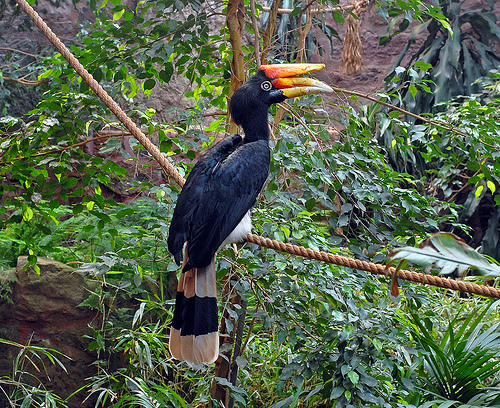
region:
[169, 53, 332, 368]
A horn bill in the wild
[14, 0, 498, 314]
A twisted horizontal rope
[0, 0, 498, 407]
The green vegetated grounds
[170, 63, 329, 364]
A long tailed hornbill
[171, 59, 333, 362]
The orange beaked hornbill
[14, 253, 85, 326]
The gray weather beaten rock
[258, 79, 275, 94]
The rounded horn-bill eyes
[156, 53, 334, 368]
The young black and white horn-bill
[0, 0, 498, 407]
The dirt covered background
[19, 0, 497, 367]
A young horn-bill on a line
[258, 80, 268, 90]
Bird has blue eye.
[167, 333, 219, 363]
Tip of tail feathers are tan.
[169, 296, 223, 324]
Black stripe on tail feathers.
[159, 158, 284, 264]
Large bird perched on rope.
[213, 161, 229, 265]
Black feathers on bird's wing.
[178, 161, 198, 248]
Black feathers on bird's wing.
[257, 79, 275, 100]
Yellow ring around bird's eye.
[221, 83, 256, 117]
Bird has black head.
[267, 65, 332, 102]
Bird has red and orange beak.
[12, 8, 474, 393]
ground covered with dirt, rocks and green plants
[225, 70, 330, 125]
round black head with orange beak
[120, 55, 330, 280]
large bird perched on brown rope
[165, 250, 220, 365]
thick black stripe across white tail feathers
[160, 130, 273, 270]
long black wings close to bird's body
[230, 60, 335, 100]
flat orange appendage over beak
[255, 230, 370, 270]
line of slants across brown rope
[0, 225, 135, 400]
gray rock surrounded by narrow and triangular leaves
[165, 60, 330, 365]
black and white bird balanced on twisted fibers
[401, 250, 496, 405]
plant with long and narrow leaves growing under rope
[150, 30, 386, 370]
A very large bird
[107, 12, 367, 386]
A bird sitting on a rope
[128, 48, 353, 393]
Large black and white bird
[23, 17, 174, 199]
A large rope hanging from one to the other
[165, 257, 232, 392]
Long black and white tail feathers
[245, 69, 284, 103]
Birds white eye with a orange ring around it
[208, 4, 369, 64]
A tree on other side of bird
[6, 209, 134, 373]
A grey rock on other side of bird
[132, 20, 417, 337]
this is a bird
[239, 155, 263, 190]
the bird is black in color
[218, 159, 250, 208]
this is the wing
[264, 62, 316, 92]
this is the beak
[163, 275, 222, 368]
this is the tail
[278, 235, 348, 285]
this is the rope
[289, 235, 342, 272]
the rope is brown in color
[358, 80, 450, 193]
this is a tree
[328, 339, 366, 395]
these are the leaves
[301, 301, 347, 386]
the leaves are green in color